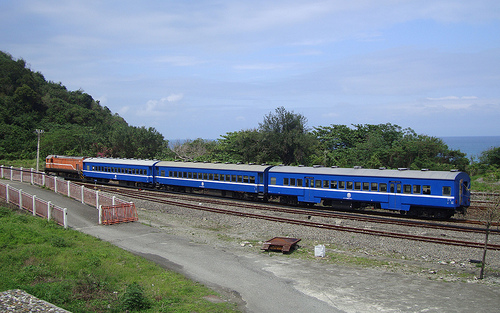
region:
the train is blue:
[78, 158, 470, 221]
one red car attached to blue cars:
[44, 151, 469, 219]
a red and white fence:
[0, 172, 142, 232]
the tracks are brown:
[78, 168, 498, 249]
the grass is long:
[0, 204, 241, 311]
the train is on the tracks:
[34, 157, 497, 249]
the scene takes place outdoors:
[0, 0, 497, 310]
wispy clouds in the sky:
[1, 0, 496, 140]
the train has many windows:
[46, 156, 470, 208]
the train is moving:
[48, 153, 470, 221]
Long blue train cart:
[262, 152, 467, 227]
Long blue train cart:
[155, 150, 270, 205]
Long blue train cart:
[81, 153, 157, 192]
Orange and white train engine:
[38, 143, 85, 188]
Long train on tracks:
[35, 135, 446, 218]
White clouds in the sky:
[435, 76, 479, 123]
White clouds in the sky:
[451, 48, 485, 75]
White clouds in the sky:
[379, 40, 411, 80]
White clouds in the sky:
[319, 49, 371, 96]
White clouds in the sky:
[297, 20, 347, 72]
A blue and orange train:
[42, 152, 474, 212]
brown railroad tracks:
[66, 173, 498, 254]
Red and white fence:
[0, 160, 137, 226]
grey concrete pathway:
[0, 171, 345, 307]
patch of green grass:
[0, 198, 238, 309]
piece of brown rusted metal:
[258, 233, 299, 254]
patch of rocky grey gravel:
[117, 195, 495, 263]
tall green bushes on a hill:
[0, 50, 171, 155]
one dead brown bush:
[170, 133, 217, 159]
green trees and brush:
[216, 104, 467, 166]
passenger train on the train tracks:
[48, 146, 473, 218]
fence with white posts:
[13, 163, 135, 238]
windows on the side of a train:
[166, 168, 256, 193]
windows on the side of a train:
[273, 174, 442, 201]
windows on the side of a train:
[87, 161, 157, 183]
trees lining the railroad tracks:
[5, 42, 478, 189]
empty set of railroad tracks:
[207, 202, 492, 284]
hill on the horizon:
[423, 116, 493, 171]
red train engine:
[42, 147, 82, 179]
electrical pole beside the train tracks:
[29, 117, 51, 179]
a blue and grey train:
[83, 155, 473, 222]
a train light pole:
[33, 126, 45, 170]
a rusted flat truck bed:
[261, 234, 301, 256]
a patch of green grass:
[0, 205, 203, 311]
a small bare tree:
[462, 186, 497, 280]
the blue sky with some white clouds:
[0, 0, 495, 136]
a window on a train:
[421, 184, 432, 195]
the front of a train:
[423, 165, 471, 216]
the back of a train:
[78, 155, 110, 178]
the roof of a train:
[267, 161, 460, 180]